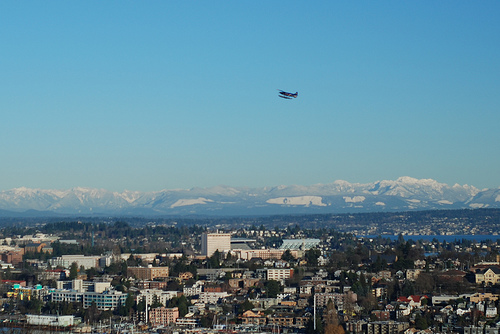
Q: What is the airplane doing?
A: Flying.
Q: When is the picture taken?
A: Daytime.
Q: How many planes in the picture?
A: 1.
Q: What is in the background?
A: Mountains.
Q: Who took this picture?
A: Photographer.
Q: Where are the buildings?
A: On the ground.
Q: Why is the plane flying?
A: Traveling.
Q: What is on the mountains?
A: Snow.